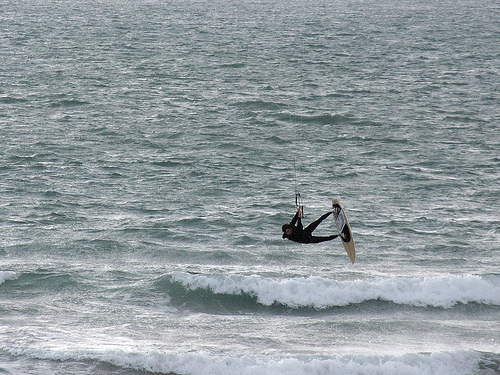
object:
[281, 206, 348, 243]
person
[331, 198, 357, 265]
surfboard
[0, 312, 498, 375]
waves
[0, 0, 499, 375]
water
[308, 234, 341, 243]
legs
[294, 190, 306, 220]
handle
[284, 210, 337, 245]
wetsuit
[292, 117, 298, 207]
strings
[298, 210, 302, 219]
hands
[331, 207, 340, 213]
feet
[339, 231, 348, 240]
right foot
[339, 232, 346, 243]
foot straps